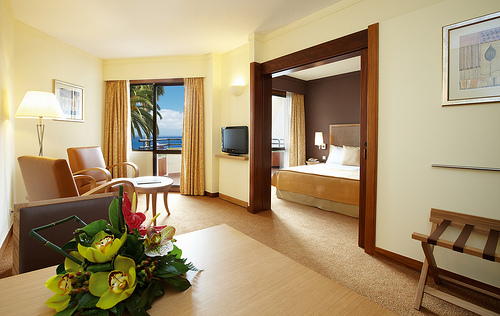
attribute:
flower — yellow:
[77, 229, 128, 264]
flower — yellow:
[88, 253, 137, 309]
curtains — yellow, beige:
[178, 78, 206, 196]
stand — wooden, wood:
[413, 215, 499, 315]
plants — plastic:
[30, 185, 198, 316]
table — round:
[136, 176, 174, 216]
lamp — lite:
[20, 92, 68, 158]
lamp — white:
[313, 132, 325, 151]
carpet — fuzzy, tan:
[305, 230, 354, 267]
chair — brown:
[20, 156, 71, 199]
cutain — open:
[107, 81, 130, 164]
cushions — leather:
[68, 147, 106, 180]